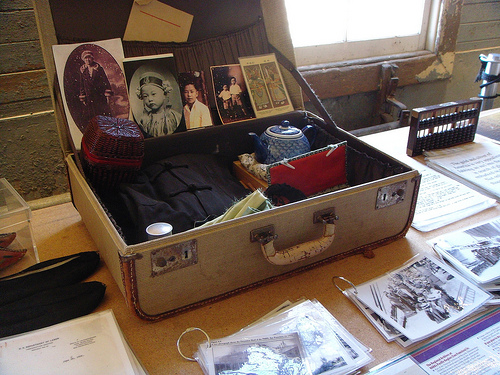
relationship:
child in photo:
[216, 81, 231, 112] [211, 61, 256, 122]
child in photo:
[228, 76, 249, 114] [211, 61, 256, 122]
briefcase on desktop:
[29, 0, 420, 323] [8, 110, 496, 373]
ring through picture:
[174, 325, 211, 361] [342, 214, 499, 348]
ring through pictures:
[324, 265, 360, 297] [193, 293, 374, 373]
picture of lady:
[68, 37, 125, 147] [74, 51, 114, 116]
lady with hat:
[74, 51, 114, 116] [79, 49, 92, 58]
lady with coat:
[74, 51, 114, 116] [77, 62, 113, 119]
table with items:
[2, 172, 462, 372] [6, 89, 484, 364]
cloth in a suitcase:
[109, 149, 249, 242] [31, 0, 422, 322]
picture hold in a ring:
[342, 214, 499, 348] [324, 265, 360, 297]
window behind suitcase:
[286, 1, 446, 61] [55, 100, 497, 325]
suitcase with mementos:
[31, 0, 422, 322] [45, 7, 373, 237]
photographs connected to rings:
[171, 207, 452, 373] [160, 260, 365, 360]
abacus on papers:
[391, 93, 492, 174] [422, 139, 499, 229]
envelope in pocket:
[113, 3, 185, 46] [58, 26, 268, 113]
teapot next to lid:
[247, 118, 330, 166] [267, 140, 350, 190]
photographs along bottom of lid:
[47, 33, 300, 146] [27, 0, 312, 155]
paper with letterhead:
[434, 141, 497, 197] [13, 318, 150, 373]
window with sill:
[257, 0, 465, 99] [305, 47, 463, 99]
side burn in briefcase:
[246, 115, 316, 167] [29, 0, 444, 328]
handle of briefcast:
[251, 208, 341, 266] [31, 7, 416, 322]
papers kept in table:
[3, 301, 141, 372] [2, 172, 462, 372]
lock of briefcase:
[374, 178, 419, 215] [29, 0, 444, 328]